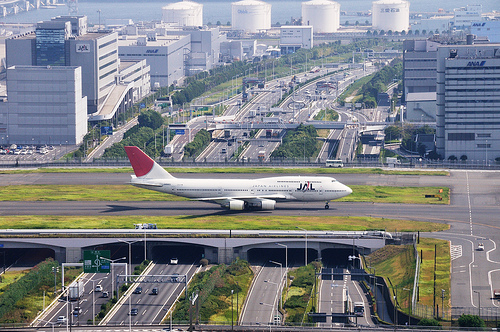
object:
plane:
[123, 142, 354, 212]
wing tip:
[125, 176, 136, 188]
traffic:
[79, 249, 181, 274]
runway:
[0, 199, 492, 217]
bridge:
[0, 156, 385, 270]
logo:
[297, 180, 316, 193]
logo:
[75, 43, 90, 52]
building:
[4, 16, 153, 132]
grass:
[5, 217, 353, 229]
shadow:
[94, 202, 338, 222]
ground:
[0, 163, 499, 318]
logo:
[466, 61, 486, 67]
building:
[433, 50, 499, 163]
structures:
[158, 0, 204, 31]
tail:
[121, 144, 171, 191]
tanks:
[228, 0, 274, 32]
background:
[0, 1, 500, 110]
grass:
[18, 188, 445, 201]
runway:
[10, 174, 450, 184]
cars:
[150, 287, 159, 296]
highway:
[38, 254, 150, 319]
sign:
[82, 250, 111, 273]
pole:
[60, 265, 66, 293]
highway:
[97, 255, 197, 327]